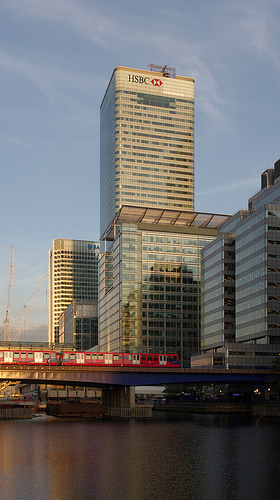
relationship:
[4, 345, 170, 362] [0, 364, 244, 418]
train on bridge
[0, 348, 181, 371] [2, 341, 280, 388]
train on bridge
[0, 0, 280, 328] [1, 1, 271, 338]
cloud in sky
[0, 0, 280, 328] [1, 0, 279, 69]
cloud in sky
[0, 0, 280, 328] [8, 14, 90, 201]
cloud in blue sky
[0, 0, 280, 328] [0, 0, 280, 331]
cloud in blue sky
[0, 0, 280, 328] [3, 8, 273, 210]
cloud in sky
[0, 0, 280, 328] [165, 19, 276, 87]
cloud in blue sky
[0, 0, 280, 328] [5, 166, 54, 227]
cloud in sky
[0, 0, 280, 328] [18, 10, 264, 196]
cloud in sky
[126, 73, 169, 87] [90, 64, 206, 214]
writting attached to building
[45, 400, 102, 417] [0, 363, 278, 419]
bridge running underneath bridge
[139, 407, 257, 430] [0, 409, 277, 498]
reflection appearing in water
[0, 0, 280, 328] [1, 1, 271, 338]
cloud hanging in sky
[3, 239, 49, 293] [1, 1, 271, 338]
cloud hanging in sky